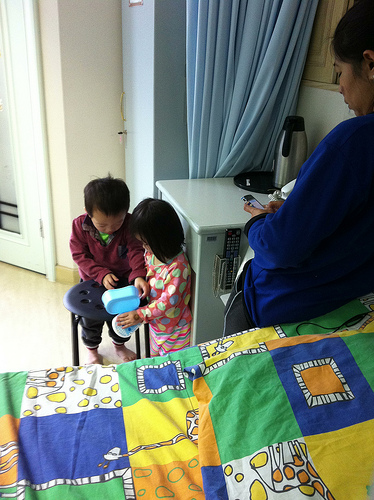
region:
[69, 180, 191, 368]
the kids are playing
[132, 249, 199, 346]
the shirt is polka dots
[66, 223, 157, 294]
the jacket is maroon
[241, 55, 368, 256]
woman is looking at the phone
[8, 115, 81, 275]
the door is white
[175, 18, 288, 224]
the curtain is blue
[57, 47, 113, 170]
the wall is beige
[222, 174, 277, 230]
the phone is black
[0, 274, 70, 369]
the floor is yellow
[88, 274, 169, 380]
the container is blue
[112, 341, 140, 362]
the foot of a boy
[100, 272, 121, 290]
the hand of a boy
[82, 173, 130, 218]
the hair of a boy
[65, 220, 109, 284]
the arm of a boy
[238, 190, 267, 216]
a cell phone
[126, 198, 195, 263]
the head of a girl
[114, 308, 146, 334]
the hand of a girl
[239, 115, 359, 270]
the arm of a woman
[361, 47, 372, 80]
the ear of a woman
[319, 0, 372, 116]
the head of a woman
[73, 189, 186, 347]
Brother and sister playing.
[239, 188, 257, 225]
The woman has cell phone in her hand.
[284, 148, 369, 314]
The jacket is blue.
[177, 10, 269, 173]
The curtain is blue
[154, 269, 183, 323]
The girl has polka dots on shirt.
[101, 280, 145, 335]
The girl is holding a blue object.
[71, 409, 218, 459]
Giraffe on the blanket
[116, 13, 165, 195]
a white long cabinet.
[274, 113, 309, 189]
The water pot is silver.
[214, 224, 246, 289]
the remote is on the side of the mini frig.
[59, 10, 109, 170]
white wall in room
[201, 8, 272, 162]
blue curtain in kitchen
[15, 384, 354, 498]
multi colored quilt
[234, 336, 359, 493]
multi colored quilt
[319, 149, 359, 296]
woman wearing blue jacket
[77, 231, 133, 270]
boy wearing green shirt and burgundy jacket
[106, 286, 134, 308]
boy holding blue bowl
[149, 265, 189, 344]
young girl wearing multicolored shirt and pants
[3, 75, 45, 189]
white wall in room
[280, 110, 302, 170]
silver and black pitcher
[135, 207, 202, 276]
Person has dark hair.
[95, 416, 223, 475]
Giraffe on bedspread.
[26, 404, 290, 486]
Blue, green, yellow, and orange bedspread.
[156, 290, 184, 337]
Girl wearing pink polka dot shirt.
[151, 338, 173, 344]
Girl wearing stripe pants.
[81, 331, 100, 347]
Boy wearing dark pants.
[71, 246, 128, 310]
Boy wearing red shirt.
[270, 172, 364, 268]
Person wearing blue shirt.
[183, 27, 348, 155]
Blue curtain pushed back by wall.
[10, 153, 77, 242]
White door behind kids.